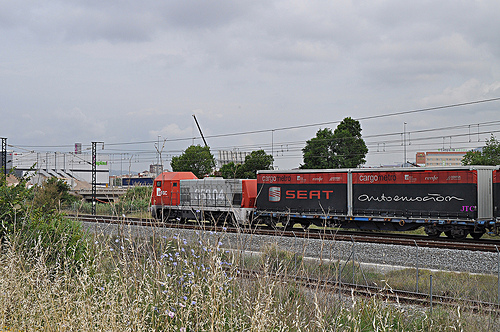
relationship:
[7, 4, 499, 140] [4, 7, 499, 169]
cloud in sky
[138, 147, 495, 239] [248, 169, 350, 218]
train has cart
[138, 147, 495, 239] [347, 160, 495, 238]
train has car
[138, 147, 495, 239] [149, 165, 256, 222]
train has car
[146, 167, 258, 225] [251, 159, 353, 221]
engine pulling car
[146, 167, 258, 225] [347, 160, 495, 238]
engine pulling car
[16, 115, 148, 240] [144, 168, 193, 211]
building in front of red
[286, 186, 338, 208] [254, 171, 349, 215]
red letters on background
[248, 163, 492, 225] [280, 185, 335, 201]
cart says sert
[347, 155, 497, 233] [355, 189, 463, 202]
car with writing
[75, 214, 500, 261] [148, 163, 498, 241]
gravel around train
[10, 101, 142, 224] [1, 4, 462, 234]
structure in background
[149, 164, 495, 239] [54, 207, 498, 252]
train on tracks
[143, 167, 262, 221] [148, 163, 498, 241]
engine of a train